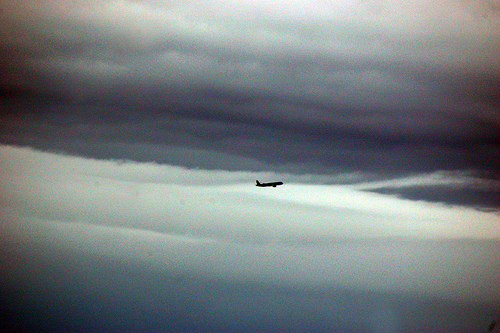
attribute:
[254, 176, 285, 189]
plane — far aero, flying, aero, airplane, high, far away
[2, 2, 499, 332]
sky — beautiful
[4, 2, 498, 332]
clouds — beautiful, clear, black, dark, white, very dark, grayish, rain clouds, rain cloud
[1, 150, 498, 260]
cloud — white